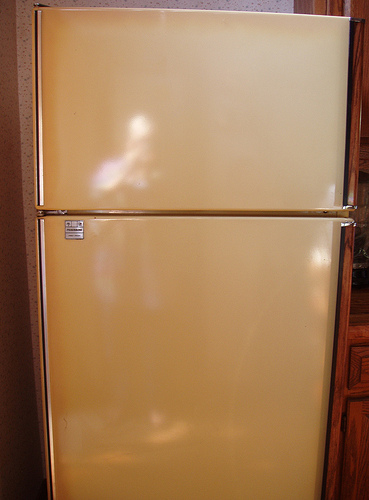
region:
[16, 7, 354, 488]
tan two-door refrigerator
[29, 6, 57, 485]
black and silver stripe along edge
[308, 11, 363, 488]
wooden handles along edge of door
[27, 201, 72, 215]
silver hinge between doors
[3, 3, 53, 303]
white wall covering with gold dots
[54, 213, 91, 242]
square metal plate with information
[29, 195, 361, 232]
narrow space between two doors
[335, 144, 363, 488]
wood cabinets next to refrigerator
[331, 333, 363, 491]
drawer and door on cabinet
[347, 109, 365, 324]
open storage space in cabinet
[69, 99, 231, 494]
reflection of man on fridge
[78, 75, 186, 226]
man is holding camera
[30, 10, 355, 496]
the fridge is yellow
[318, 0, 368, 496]
cabinets are made of wood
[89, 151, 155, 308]
man's shirt is blue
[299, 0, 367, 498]
cabinets are brown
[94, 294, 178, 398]
pants are dark colored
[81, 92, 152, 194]
the person is white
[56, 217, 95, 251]
silver magnet on fridge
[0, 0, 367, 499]
an image of a refrigerator in a kitchen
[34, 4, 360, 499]
a gold color refrigerator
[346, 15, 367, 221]
wood hinges and trim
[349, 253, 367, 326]
a wooden kitchen counter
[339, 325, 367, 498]
a wooden kitchen drawers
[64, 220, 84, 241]
the brand name mounted on the refrigerator door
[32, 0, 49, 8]
metal door hinge for the refrigerator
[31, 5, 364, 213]
the top freezer section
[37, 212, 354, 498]
the bottom refrigerator section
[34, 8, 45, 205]
the metal trim of the freezer door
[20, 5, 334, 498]
A tan refridgerator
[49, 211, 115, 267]
Refridgerator has silver square on it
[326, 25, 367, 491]
Refridgerator has brown handles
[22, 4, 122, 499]
Refridgerator has silver and black stripe down the side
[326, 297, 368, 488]
Cabinet and drawer next to refridgerator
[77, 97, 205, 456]
Reflection of a person on the fridge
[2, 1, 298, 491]
White wall with speckles behind fridge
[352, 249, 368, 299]
A glass jar on the counter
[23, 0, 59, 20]
Silver piece at top of fridge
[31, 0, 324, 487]
Two doors on fridge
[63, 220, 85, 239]
A metal fridge posting.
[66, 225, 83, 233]
Small black lettering.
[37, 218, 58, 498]
Grey and steel trim.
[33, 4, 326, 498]
A cream colored fridge.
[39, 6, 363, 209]
The door for the freezer.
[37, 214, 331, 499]
The door for the fridge.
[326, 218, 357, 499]
A wooden door handle.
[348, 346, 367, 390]
A wooden cabinet drawer.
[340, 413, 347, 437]
A hnge for the cabinet.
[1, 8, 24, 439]
A speckled colored wall paper.